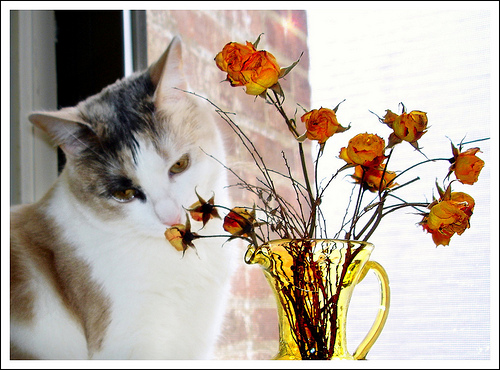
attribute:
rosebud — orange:
[157, 217, 200, 255]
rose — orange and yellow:
[418, 189, 478, 249]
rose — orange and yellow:
[238, 47, 283, 98]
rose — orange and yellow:
[159, 216, 189, 253]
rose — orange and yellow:
[226, 207, 254, 235]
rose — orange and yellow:
[393, 104, 430, 144]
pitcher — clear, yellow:
[243, 238, 391, 359]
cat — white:
[9, 36, 220, 357]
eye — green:
[168, 147, 194, 179]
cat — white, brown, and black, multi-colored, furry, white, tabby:
[7, 35, 240, 362]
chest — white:
[92, 196, 234, 360]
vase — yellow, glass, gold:
[243, 240, 393, 363]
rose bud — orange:
[215, 36, 262, 71]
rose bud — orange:
[447, 134, 486, 185]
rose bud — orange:
[380, 103, 433, 149]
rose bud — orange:
[187, 200, 207, 224]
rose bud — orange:
[301, 101, 343, 150]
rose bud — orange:
[443, 134, 488, 184]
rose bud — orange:
[374, 98, 435, 150]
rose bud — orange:
[336, 129, 386, 169]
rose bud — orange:
[298, 101, 344, 144]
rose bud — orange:
[212, 39, 256, 76]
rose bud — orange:
[451, 142, 491, 188]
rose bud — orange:
[350, 159, 401, 197]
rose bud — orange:
[339, 130, 385, 165]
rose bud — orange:
[211, 39, 248, 89]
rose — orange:
[447, 144, 487, 185]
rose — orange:
[387, 103, 434, 147]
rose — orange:
[341, 126, 393, 174]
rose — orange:
[297, 104, 347, 142]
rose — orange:
[212, 36, 241, 70]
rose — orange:
[453, 140, 487, 188]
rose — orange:
[387, 98, 433, 147]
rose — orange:
[342, 130, 388, 169]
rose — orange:
[301, 104, 336, 142]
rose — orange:
[349, 159, 393, 190]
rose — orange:
[305, 98, 344, 145]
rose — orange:
[209, 38, 242, 65]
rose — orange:
[451, 142, 489, 184]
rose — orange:
[387, 106, 433, 142]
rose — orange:
[352, 158, 401, 188]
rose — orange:
[297, 100, 341, 143]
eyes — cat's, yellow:
[102, 150, 193, 204]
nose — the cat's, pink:
[165, 210, 183, 226]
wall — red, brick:
[147, 10, 315, 120]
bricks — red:
[148, 10, 307, 89]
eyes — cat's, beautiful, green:
[102, 150, 193, 193]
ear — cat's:
[24, 109, 94, 147]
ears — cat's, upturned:
[29, 33, 189, 145]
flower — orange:
[338, 131, 389, 169]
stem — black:
[198, 198, 251, 229]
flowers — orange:
[169, 193, 247, 250]